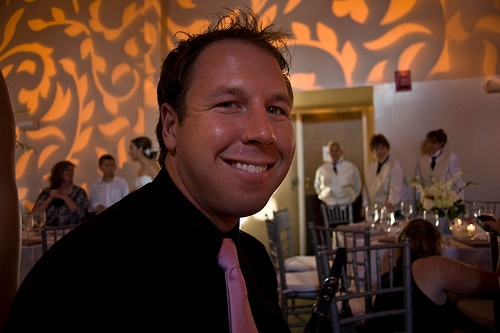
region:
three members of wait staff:
[314, 120, 466, 215]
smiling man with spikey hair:
[154, 9, 296, 226]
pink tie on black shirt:
[194, 229, 269, 331]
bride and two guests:
[37, 129, 164, 214]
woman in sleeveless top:
[377, 209, 490, 327]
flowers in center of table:
[407, 172, 472, 216]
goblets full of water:
[356, 199, 416, 234]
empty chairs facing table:
[264, 207, 334, 294]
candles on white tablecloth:
[446, 207, 487, 255]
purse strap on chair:
[297, 242, 358, 326]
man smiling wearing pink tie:
[149, 8, 260, 330]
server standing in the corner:
[298, 128, 494, 213]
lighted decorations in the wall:
[13, 12, 174, 101]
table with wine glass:
[326, 177, 493, 238]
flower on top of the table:
[407, 155, 488, 253]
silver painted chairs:
[251, 179, 392, 296]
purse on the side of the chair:
[313, 224, 342, 331]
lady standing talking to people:
[29, 124, 90, 235]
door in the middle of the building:
[294, 72, 373, 228]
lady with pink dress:
[114, 112, 155, 194]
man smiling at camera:
[131, 9, 308, 251]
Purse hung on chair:
[298, 239, 359, 331]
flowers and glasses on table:
[353, 174, 498, 247]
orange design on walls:
[1, 2, 147, 134]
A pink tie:
[208, 235, 265, 332]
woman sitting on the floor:
[367, 214, 494, 331]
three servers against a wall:
[313, 127, 470, 223]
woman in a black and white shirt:
[29, 152, 92, 228]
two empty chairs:
[263, 203, 343, 311]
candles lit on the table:
[446, 209, 497, 250]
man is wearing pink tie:
[182, 195, 262, 326]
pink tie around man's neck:
[211, 231, 266, 331]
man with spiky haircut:
[151, 6, 315, 248]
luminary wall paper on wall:
[4, 1, 154, 140]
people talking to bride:
[30, 131, 170, 218]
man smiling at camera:
[10, 15, 301, 325]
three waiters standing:
[307, 121, 471, 221]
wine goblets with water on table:
[362, 197, 434, 234]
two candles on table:
[450, 212, 481, 237]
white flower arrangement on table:
[402, 168, 469, 220]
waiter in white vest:
[307, 132, 369, 221]